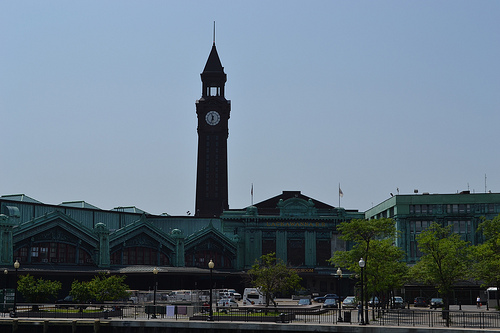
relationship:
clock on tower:
[203, 110, 220, 129] [192, 13, 237, 221]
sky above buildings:
[2, 5, 498, 214] [3, 190, 499, 293]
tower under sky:
[192, 13, 237, 221] [2, 5, 498, 214]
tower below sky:
[192, 13, 237, 221] [2, 5, 498, 214]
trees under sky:
[326, 215, 499, 308] [2, 5, 498, 214]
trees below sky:
[326, 215, 499, 308] [2, 5, 498, 214]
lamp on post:
[355, 257, 365, 272] [355, 267, 366, 330]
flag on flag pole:
[336, 183, 344, 199] [339, 182, 341, 216]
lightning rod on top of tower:
[207, 17, 225, 47] [192, 13, 237, 221]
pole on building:
[330, 181, 347, 218] [214, 183, 376, 286]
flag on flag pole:
[330, 182, 343, 199] [333, 178, 348, 216]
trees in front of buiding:
[326, 215, 499, 308] [176, 262, 374, 301]